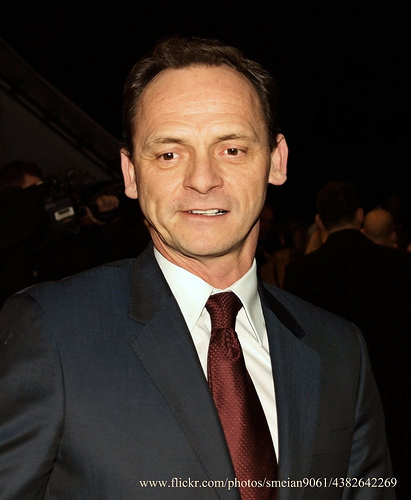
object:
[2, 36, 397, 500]
man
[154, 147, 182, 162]
eye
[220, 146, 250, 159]
eye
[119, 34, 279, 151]
hair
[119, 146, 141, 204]
ear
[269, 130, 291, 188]
ear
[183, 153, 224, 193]
nose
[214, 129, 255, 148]
eyebrow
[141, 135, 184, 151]
eyebrow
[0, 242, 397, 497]
jacket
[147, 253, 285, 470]
shirt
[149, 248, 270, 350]
collar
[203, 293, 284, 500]
necktie